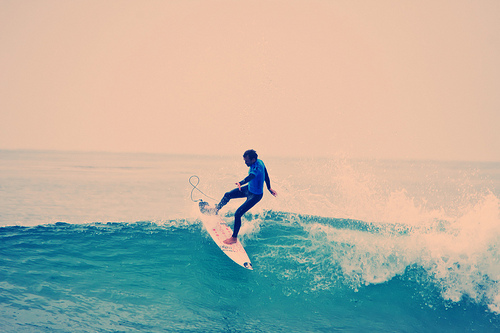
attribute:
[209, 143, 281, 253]
man — is watching shoreline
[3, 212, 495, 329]
wave — is moving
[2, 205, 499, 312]
wave — moving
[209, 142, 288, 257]
man — surfing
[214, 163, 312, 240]
costume — blue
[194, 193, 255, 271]
surf board — white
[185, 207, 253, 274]
surfboard — white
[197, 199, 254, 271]
surf board — is white, is blue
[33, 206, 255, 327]
water — green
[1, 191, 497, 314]
wave — high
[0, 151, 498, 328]
water — splashing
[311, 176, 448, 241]
mist — is splashing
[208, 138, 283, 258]
man — is watching water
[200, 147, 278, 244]
he — standing